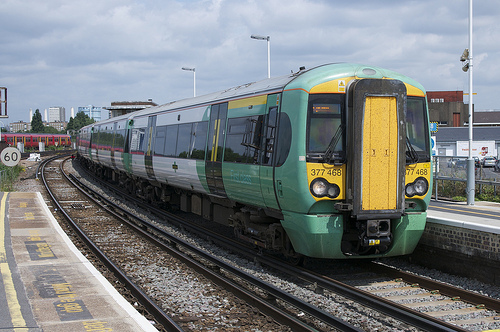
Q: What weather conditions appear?
A: It is overcast.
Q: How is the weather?
A: It is overcast.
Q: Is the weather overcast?
A: Yes, it is overcast.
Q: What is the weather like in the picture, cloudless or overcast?
A: It is overcast.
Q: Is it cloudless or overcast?
A: It is overcast.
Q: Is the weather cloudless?
A: No, it is overcast.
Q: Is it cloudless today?
A: No, it is overcast.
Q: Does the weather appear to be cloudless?
A: No, it is overcast.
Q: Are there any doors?
A: Yes, there is a door.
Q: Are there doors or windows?
A: Yes, there is a door.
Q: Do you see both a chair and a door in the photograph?
A: No, there is a door but no chairs.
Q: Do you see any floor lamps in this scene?
A: No, there are no floor lamps.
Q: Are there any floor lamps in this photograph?
A: No, there are no floor lamps.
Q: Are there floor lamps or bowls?
A: No, there are no floor lamps or bowls.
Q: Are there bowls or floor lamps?
A: No, there are no floor lamps or bowls.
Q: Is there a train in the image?
A: Yes, there is a train.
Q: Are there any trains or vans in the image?
A: Yes, there is a train.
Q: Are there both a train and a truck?
A: No, there is a train but no trucks.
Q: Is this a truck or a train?
A: This is a train.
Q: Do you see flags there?
A: No, there are no flags.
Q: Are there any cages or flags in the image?
A: No, there are no flags or cages.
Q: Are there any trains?
A: Yes, there is a train.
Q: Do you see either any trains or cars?
A: Yes, there is a train.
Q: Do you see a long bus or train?
A: Yes, there is a long train.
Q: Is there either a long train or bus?
A: Yes, there is a long train.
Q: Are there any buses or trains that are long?
A: Yes, the train is long.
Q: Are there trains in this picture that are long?
A: Yes, there is a long train.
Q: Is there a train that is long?
A: Yes, there is a train that is long.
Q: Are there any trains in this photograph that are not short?
A: Yes, there is a long train.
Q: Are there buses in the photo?
A: No, there are no buses.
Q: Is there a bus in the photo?
A: No, there are no buses.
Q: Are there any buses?
A: No, there are no buses.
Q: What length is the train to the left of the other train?
A: The train is long.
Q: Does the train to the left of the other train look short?
A: No, the train is long.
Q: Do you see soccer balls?
A: No, there are no soccer balls.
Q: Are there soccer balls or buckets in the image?
A: No, there are no soccer balls or buckets.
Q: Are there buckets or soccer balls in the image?
A: No, there are no soccer balls or buckets.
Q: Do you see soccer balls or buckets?
A: No, there are no soccer balls or buckets.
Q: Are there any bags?
A: No, there are no bags.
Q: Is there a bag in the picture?
A: No, there are no bags.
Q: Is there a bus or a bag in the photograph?
A: No, there are no bags or buses.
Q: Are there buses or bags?
A: No, there are no bags or buses.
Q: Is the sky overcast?
A: Yes, the sky is overcast.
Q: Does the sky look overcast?
A: Yes, the sky is overcast.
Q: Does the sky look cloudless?
A: No, the sky is overcast.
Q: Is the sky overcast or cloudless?
A: The sky is overcast.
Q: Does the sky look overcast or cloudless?
A: The sky is overcast.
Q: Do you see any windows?
A: Yes, there are windows.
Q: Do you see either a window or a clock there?
A: Yes, there are windows.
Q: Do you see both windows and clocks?
A: No, there are windows but no clocks.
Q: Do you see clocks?
A: No, there are no clocks.